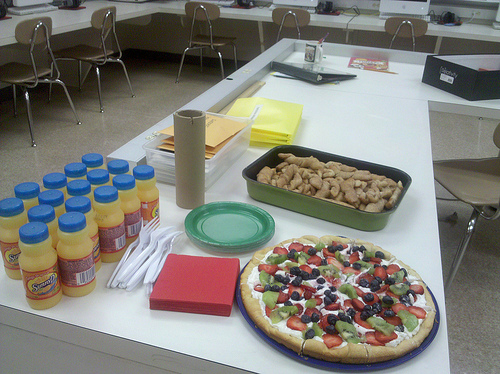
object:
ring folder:
[279, 63, 357, 89]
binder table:
[245, 97, 304, 147]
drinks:
[2, 152, 159, 309]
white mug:
[303, 40, 324, 63]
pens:
[317, 32, 330, 43]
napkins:
[148, 253, 241, 316]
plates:
[185, 198, 275, 248]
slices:
[237, 232, 441, 365]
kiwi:
[270, 304, 295, 324]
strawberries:
[365, 327, 395, 344]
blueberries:
[359, 302, 383, 320]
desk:
[0, 37, 500, 371]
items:
[269, 54, 358, 83]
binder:
[268, 57, 357, 85]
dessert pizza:
[240, 233, 439, 371]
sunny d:
[2, 151, 168, 309]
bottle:
[91, 184, 129, 263]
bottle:
[130, 164, 162, 226]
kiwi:
[307, 299, 317, 310]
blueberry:
[326, 244, 336, 254]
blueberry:
[375, 251, 385, 259]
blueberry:
[380, 295, 394, 303]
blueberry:
[291, 291, 300, 301]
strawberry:
[258, 263, 277, 273]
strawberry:
[288, 240, 305, 250]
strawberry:
[373, 266, 387, 278]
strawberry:
[321, 330, 343, 352]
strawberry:
[286, 315, 306, 332]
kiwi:
[266, 252, 289, 264]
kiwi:
[262, 289, 278, 309]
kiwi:
[388, 283, 410, 295]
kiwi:
[365, 249, 373, 259]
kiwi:
[395, 309, 417, 330]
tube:
[173, 107, 207, 210]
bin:
[141, 110, 255, 192]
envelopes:
[154, 110, 249, 161]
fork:
[107, 215, 185, 292]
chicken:
[256, 147, 404, 215]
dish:
[241, 143, 414, 232]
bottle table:
[0, 209, 107, 336]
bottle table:
[91, 159, 170, 224]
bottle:
[57, 211, 96, 297]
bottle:
[16, 222, 62, 309]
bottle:
[0, 198, 26, 279]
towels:
[171, 109, 206, 211]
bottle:
[111, 172, 142, 241]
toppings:
[255, 239, 422, 347]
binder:
[226, 97, 305, 147]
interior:
[267, 159, 273, 166]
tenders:
[277, 163, 324, 188]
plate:
[236, 233, 441, 371]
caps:
[59, 211, 85, 231]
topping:
[250, 272, 257, 280]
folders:
[225, 93, 302, 145]